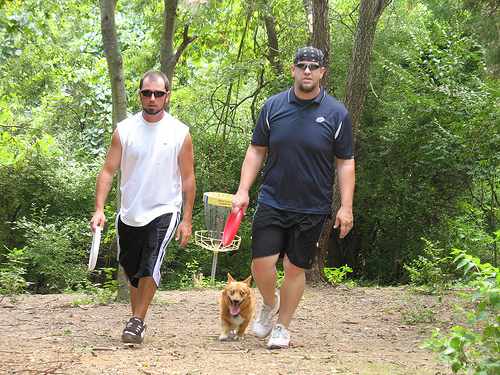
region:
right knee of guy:
[247, 238, 292, 295]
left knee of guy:
[270, 240, 312, 362]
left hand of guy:
[322, 191, 389, 253]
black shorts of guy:
[240, 200, 337, 264]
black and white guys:
[100, 218, 212, 280]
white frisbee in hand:
[77, 205, 140, 296]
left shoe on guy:
[102, 311, 173, 343]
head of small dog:
[217, 273, 259, 318]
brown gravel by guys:
[329, 270, 461, 372]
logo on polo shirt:
[288, 100, 345, 140]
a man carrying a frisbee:
[218, 44, 357, 350]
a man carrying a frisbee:
[84, 68, 196, 348]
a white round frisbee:
[84, 225, 103, 272]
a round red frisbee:
[221, 205, 242, 247]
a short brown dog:
[217, 272, 255, 342]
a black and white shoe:
[118, 314, 147, 348]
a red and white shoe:
[263, 323, 291, 350]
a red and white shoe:
[250, 293, 281, 341]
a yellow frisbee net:
[197, 190, 244, 285]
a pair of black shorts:
[243, 199, 334, 269]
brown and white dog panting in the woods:
[201, 270, 254, 339]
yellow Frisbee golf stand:
[192, 186, 249, 289]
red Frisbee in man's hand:
[212, 186, 248, 253]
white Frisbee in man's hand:
[80, 220, 105, 270]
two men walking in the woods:
[87, 43, 357, 352]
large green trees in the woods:
[12, 3, 454, 272]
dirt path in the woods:
[34, 279, 428, 369]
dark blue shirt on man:
[243, 92, 354, 222]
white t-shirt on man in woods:
[106, 116, 190, 227]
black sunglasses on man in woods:
[290, 61, 329, 72]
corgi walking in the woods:
[211, 267, 258, 347]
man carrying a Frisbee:
[83, 65, 196, 350]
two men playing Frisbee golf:
[78, 38, 369, 360]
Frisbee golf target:
[191, 183, 253, 293]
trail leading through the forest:
[0, 262, 499, 371]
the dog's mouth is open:
[208, 272, 264, 345]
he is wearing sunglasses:
[280, 44, 332, 105]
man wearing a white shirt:
[63, 63, 201, 350]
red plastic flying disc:
[213, 184, 255, 259]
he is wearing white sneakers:
[249, 287, 300, 355]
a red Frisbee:
[222, 200, 249, 246]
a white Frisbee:
[82, 225, 104, 271]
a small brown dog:
[210, 274, 260, 341]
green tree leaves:
[404, 235, 447, 290]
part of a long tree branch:
[337, 0, 394, 129]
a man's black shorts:
[248, 195, 328, 266]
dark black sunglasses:
[294, 60, 320, 71]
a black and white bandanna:
[292, 45, 323, 65]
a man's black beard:
[138, 102, 163, 114]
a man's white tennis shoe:
[263, 316, 293, 353]